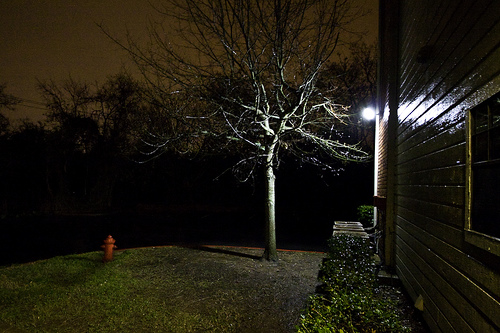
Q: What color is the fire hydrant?
A: Red.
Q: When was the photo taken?
A: Night time.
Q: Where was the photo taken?
A: Outside the building.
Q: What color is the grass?
A: Green.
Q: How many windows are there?
A: One.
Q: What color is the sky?
A: Orange.